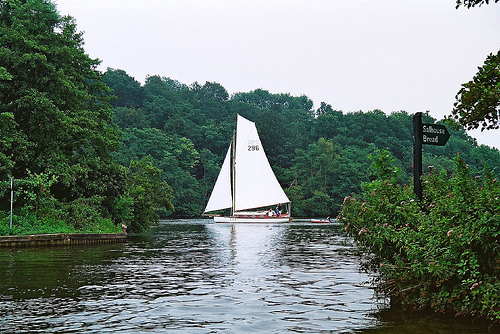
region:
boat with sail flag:
[194, 97, 314, 237]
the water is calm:
[187, 234, 309, 303]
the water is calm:
[131, 240, 306, 327]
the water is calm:
[142, 268, 282, 318]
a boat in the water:
[183, 76, 335, 296]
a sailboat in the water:
[189, 75, 361, 315]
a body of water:
[117, 215, 363, 332]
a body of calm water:
[119, 213, 275, 332]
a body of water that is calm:
[137, 226, 272, 320]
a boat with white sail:
[197, 80, 322, 281]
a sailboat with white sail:
[147, 76, 372, 328]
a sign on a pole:
[373, 92, 495, 292]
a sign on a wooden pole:
[388, 87, 443, 213]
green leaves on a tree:
[97, 58, 410, 229]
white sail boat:
[140, 106, 298, 243]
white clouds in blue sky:
[115, 15, 182, 65]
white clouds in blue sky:
[310, 32, 384, 86]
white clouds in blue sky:
[370, 22, 448, 73]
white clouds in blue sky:
[291, 35, 336, 85]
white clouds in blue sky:
[191, 3, 236, 57]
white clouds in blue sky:
[260, 16, 341, 64]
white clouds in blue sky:
[354, 32, 396, 83]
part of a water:
[187, 249, 224, 294]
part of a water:
[256, 272, 279, 293]